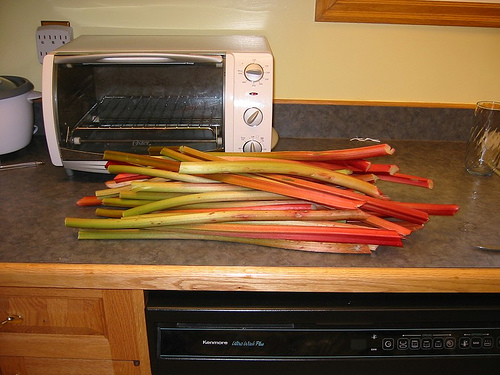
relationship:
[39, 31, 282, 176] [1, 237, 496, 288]
oven on counter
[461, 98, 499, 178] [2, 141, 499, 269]
glass on counter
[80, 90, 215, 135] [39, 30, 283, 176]
rack on oven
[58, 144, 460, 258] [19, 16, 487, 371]
stick in kitchen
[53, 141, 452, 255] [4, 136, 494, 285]
vegetable are lying on counter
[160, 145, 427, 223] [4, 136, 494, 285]
vegetable are lying on counter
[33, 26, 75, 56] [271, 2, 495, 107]
outlet plugged into wall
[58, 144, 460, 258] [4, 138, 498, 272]
stick on table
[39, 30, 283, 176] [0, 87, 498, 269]
oven on counter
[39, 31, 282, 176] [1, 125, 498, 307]
oven in kitchen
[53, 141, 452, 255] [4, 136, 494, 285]
vegetable on counter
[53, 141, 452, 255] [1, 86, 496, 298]
vegetable on counter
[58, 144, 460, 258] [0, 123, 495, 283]
stick on counter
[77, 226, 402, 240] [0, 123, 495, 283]
stick on counter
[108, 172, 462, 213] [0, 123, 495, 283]
stick on counter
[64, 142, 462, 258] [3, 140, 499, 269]
rhubarb on counter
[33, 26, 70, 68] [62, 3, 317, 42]
outlet on wall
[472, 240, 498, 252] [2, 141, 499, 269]
spoon on counter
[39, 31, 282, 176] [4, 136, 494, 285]
oven sitting on counter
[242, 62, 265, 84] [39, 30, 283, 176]
knob on right side of oven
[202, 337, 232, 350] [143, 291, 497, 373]
kenmore on dishwasher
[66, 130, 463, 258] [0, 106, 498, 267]
food on table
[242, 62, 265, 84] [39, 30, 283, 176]
knob on oven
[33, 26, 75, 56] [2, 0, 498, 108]
outlet on wall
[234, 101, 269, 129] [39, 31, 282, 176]
knob on oven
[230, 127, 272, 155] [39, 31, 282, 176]
knob on oven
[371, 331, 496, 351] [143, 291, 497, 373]
buttons on dishwasher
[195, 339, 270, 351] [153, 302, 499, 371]
words on dishwasher